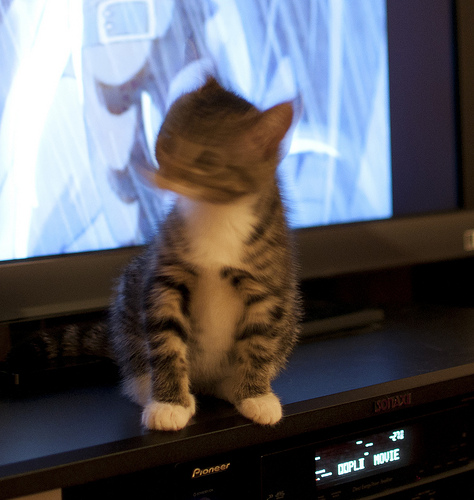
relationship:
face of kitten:
[151, 73, 295, 203] [112, 73, 301, 431]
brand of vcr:
[190, 462, 231, 477] [62, 391, 473, 500]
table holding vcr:
[2, 303, 473, 499] [62, 391, 473, 500]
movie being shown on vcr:
[1, 0, 391, 259] [62, 391, 473, 500]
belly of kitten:
[177, 193, 260, 380] [112, 73, 301, 431]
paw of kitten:
[141, 392, 196, 430] [112, 73, 301, 431]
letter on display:
[372, 454, 381, 466] [312, 424, 414, 486]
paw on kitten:
[141, 392, 196, 430] [112, 73, 301, 431]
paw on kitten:
[235, 392, 282, 426] [112, 73, 301, 431]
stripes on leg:
[143, 253, 200, 369] [140, 257, 199, 430]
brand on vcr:
[190, 462, 231, 477] [62, 391, 473, 500]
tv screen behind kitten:
[1, 1, 465, 263] [112, 73, 301, 431]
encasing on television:
[1, 0, 473, 323] [0, 0, 473, 337]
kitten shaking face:
[112, 73, 301, 431] [151, 73, 295, 203]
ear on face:
[247, 100, 293, 160] [151, 73, 295, 203]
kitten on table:
[112, 73, 301, 431] [2, 303, 473, 499]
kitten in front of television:
[112, 73, 301, 431] [0, 0, 473, 337]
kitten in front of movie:
[112, 73, 301, 431] [1, 0, 391, 259]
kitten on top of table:
[112, 73, 301, 431] [2, 303, 473, 499]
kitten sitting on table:
[112, 73, 301, 431] [2, 303, 473, 499]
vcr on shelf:
[62, 391, 473, 500] [363, 460, 472, 500]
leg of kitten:
[140, 257, 199, 430] [112, 73, 301, 431]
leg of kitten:
[218, 267, 285, 424] [112, 73, 301, 431]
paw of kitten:
[235, 392, 282, 426] [112, 73, 301, 431]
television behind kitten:
[0, 0, 473, 337] [112, 73, 301, 431]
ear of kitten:
[247, 100, 293, 160] [112, 73, 301, 431]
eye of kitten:
[195, 149, 221, 174] [112, 73, 301, 431]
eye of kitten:
[159, 128, 175, 154] [112, 73, 301, 431]